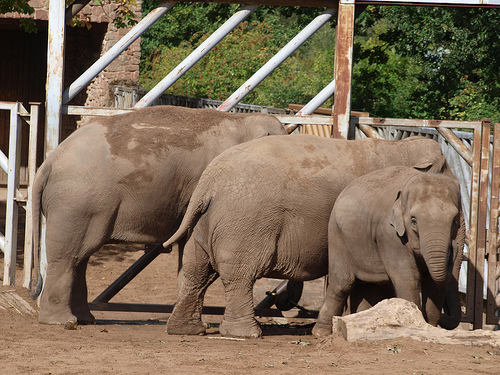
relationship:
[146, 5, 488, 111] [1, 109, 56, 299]
trees behind fence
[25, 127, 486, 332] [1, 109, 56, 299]
elephants near fence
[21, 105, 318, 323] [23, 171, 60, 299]
elephant has tail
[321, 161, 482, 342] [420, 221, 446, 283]
elephant has trunk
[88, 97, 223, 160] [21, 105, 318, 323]
dirt on elephant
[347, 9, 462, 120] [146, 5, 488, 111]
leaves on trees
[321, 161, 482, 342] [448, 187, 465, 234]
elephant has ear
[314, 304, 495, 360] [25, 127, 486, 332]
log near elephants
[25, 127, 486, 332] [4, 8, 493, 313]
elephants in enclosure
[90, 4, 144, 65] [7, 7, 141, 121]
lantern on wall